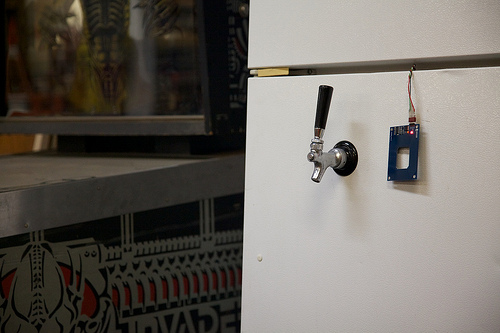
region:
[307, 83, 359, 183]
this is a tap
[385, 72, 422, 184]
this is a cable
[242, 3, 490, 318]
this is a fridge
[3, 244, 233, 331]
these are drawings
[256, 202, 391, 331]
the fridge is white in color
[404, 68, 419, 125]
this is a wire connecting to the cable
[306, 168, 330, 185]
this is the tap nozzle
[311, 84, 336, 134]
the tap's switch is black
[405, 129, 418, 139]
this is a red light flicking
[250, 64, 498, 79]
this is space between the fridge's door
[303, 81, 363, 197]
Beverage tap/lever attached to white door.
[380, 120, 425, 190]
Electrical blue board attached to white door.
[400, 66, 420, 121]
Cable wires attached to blue electrical board on white door.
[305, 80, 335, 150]
Black and silver lever that can be pulled on the lever/tap attached to the door.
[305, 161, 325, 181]
Open spout where the liquid will come out of on the lever/tap.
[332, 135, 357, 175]
Round circle attached to white door on lever/tap.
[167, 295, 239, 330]
Letters ADE on the side of the table.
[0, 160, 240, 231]
Metal siding of the table.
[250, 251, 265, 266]
White screw on the white door.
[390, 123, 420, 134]
Red lights on blue electrical board.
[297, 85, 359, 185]
silver and black tap on frigde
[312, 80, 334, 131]
tap has black handle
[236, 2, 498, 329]
fridge plain white and clean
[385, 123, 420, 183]
blue electric item hanging out of fridge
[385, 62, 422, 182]
blue electric item connected to wires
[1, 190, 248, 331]
green and red pattern under counter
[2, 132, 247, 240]
silver counter near fridge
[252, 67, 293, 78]
yellow square in gap between fridge and freezer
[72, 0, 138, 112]
yellow and black decoration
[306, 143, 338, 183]
tap has silver nozzle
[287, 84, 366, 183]
This is a faucet.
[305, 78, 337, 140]
This is a faucet handle.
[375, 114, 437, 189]
This is a key card.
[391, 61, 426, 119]
This is a lanyard.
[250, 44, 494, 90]
This is a pole.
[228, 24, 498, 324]
This is a wall.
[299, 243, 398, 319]
This is the color white.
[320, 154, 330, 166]
This is the color gray.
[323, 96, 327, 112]
This is the color black.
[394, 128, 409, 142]
This is the color blue.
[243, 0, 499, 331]
White refrigerator front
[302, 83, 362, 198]
Black and silver tap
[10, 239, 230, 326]
Black, white and red pattern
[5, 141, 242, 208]
Stainless steel countertop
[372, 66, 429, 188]
Blue item hanging from wires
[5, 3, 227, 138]
Black frame over counter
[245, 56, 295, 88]
Refrigerator door hinge on left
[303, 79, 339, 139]
Slender black tap handle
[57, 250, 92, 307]
Black and white claw design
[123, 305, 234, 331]
Black and white writing